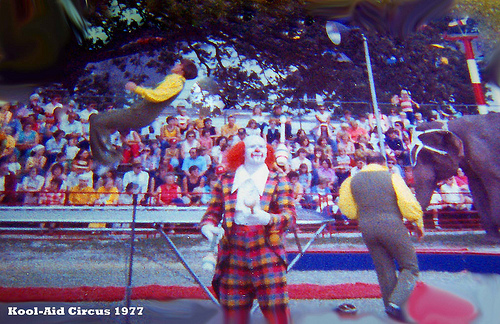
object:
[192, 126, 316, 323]
clown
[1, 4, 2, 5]
circus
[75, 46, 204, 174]
acrobat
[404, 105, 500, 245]
elephant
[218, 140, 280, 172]
red hair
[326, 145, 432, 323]
man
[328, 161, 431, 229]
shirt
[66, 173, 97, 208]
person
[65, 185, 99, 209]
yellow jacket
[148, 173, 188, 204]
woman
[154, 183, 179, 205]
red top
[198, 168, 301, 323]
squared cloths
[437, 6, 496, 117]
pole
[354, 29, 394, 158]
pole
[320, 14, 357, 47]
light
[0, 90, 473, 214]
people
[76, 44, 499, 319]
show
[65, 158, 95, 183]
man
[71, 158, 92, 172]
hat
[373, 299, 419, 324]
shoe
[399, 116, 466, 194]
head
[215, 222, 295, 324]
pants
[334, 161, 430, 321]
clothing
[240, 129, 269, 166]
painted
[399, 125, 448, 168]
decoration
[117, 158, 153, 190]
person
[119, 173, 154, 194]
white shirt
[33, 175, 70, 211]
person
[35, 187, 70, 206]
shirt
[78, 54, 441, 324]
entertainers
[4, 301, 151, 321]
letters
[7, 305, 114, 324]
kool-aid circus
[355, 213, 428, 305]
pants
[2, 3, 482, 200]
air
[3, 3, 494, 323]
picture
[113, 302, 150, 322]
1977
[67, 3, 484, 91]
trees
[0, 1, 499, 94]
background